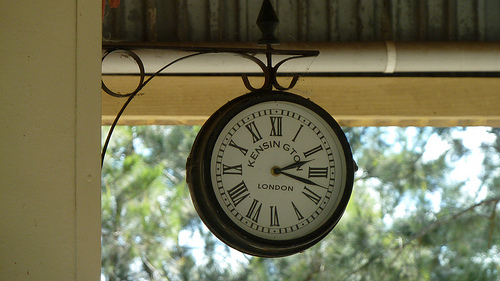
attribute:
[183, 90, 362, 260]
clock — hanging, black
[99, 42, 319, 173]
display arm — metal, clock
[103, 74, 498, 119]
beam — wood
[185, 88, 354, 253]
clock — white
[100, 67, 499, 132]
beam — wood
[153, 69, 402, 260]
clock — brown, white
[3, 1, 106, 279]
wall — white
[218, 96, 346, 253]
clock — metal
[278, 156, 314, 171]
clock hand — small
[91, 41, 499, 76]
pipe — white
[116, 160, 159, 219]
leaves — green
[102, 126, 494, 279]
leaves — green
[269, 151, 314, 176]
hand — little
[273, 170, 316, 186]
minute hand — large